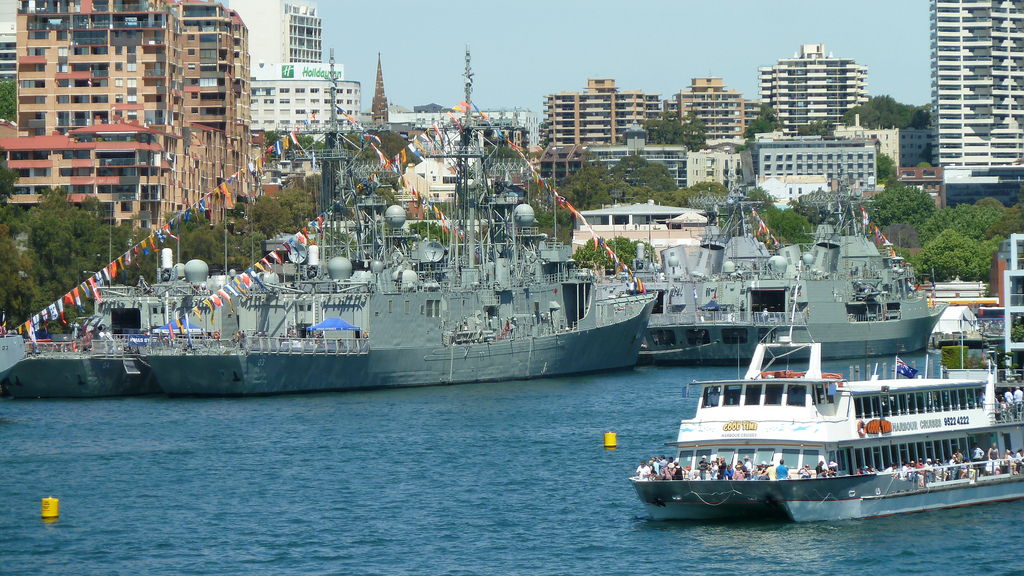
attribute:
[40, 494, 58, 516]
item — plastic, yellow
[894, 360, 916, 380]
flag — blue 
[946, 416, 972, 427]
letter — blue 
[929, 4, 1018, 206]
building — white 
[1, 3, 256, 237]
building — tan 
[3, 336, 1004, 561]
water — large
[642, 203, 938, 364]
ship — large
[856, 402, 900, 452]
logo — orange